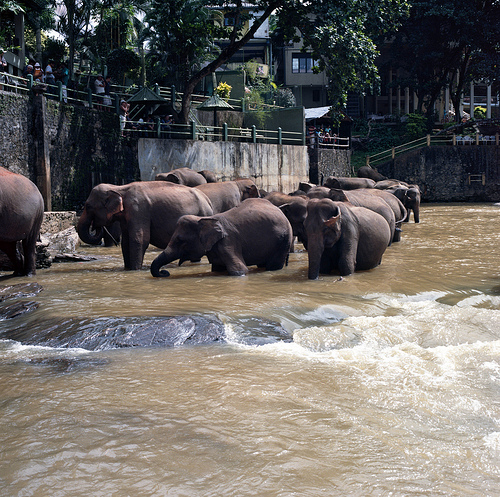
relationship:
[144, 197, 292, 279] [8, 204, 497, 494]
elephant in water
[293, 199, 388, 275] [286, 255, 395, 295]
elephant in water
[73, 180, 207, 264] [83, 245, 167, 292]
elephant in water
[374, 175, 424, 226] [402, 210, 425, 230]
elephant in water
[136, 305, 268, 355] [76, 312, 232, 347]
water pouring over rocks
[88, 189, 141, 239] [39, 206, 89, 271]
elephant near wall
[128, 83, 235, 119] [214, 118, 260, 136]
umbrella near table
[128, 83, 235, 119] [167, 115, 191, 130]
umbrella near chairs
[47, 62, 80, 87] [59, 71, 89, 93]
person wearing shirt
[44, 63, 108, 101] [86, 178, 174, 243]
people looking at elephants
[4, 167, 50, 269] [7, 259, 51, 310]
elephant in water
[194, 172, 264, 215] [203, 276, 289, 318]
elephant in water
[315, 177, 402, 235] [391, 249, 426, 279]
elephant in water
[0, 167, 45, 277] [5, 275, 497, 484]
elephant in water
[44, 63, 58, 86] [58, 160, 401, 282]
people watching elephants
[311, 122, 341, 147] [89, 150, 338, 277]
person by elephants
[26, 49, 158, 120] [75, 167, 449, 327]
people by elephants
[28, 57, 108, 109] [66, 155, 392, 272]
people by elephants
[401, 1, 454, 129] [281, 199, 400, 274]
tree behind elephant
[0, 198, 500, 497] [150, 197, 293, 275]
water near elephant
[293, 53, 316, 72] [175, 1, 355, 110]
window in building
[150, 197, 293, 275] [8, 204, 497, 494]
elephant in water